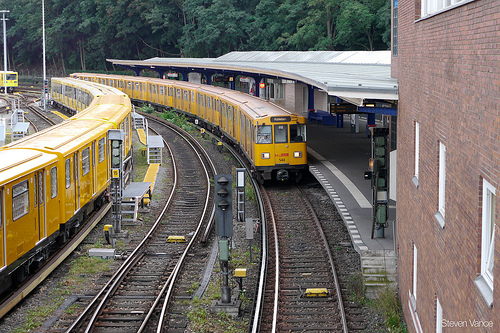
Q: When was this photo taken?
A: During the day.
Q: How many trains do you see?
A: 3.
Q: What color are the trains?
A: Yellow.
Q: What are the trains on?
A: Train tracks.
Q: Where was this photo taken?
A: Outside on the train tracks.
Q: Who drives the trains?
A: A conductor.